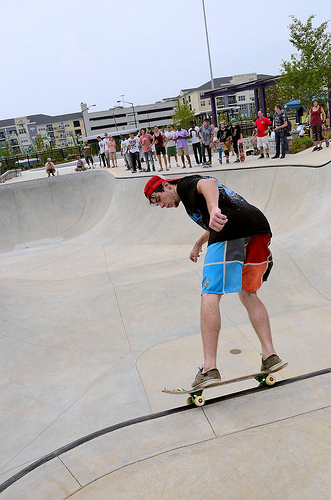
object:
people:
[271, 107, 288, 159]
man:
[142, 173, 284, 386]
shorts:
[201, 228, 274, 295]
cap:
[144, 176, 180, 198]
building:
[81, 100, 179, 155]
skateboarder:
[144, 173, 288, 388]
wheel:
[194, 394, 203, 409]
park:
[0, 0, 330, 498]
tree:
[282, 12, 330, 105]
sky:
[1, 0, 331, 122]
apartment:
[179, 72, 278, 141]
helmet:
[311, 94, 317, 102]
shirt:
[256, 116, 269, 137]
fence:
[229, 120, 257, 140]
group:
[120, 108, 289, 174]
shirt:
[309, 106, 324, 126]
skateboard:
[161, 361, 290, 406]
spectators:
[45, 157, 55, 179]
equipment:
[228, 116, 245, 162]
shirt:
[177, 176, 274, 244]